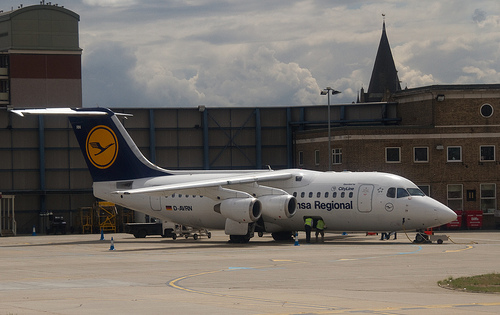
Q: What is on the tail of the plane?
A: Logo.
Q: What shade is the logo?
A: Yellow.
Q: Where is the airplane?
A: Airport.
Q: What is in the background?
A: Buildings.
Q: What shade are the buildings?
A: Brown.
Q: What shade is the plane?
A: White.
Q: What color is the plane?
A: White.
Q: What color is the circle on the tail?
A: Yellow.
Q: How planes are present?
A: 1.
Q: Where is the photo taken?
A: Runway.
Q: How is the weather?
A: Cloudy.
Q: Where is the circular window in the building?
A: Top right.